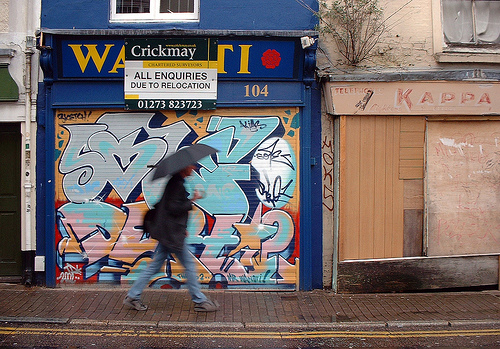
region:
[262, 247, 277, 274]
part of a graphic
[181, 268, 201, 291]
part of a jeans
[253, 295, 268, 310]
part of a floor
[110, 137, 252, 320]
A person in the foreground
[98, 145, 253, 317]
Person is walking on the sidewalk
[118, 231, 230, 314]
Person is wearing jeans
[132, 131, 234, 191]
Person is holding an umbrella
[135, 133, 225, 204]
Umbrella is black in color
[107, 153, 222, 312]
A side view of a person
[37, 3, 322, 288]
A blue colored building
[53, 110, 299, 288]
Graffiti is in the front of the building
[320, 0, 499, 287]
A tan colored building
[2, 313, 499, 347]
A long yellow line in the street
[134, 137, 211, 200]
person is holding black umbrella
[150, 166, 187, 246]
person is wearing black jacket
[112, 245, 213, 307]
person is wearing blue jeans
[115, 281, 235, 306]
person is wearing dark brown shoes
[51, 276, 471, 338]
person is walking on dark red sidewalk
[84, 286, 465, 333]
sidewalk is made of dark brown brick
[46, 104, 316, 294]
multicolor graffiti mural is behind man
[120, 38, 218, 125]
yellow and black real estate sign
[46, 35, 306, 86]
blue and yellow sign over graffiti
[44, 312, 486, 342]
double yellow line on brick sidewalk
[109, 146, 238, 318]
Woman walking down the sidewalk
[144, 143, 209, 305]
they are holding an umbrella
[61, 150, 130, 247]
graffiti on the wall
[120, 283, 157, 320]
person is wearing tennis shoes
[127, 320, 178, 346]
yellow paint on the road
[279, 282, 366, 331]
The sidewalk is uneven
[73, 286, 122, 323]
Sidewalk is made up of brick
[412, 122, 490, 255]
The door is boarded up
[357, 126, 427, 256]
Panels on the wall of building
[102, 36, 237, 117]
Realty sign on building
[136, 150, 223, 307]
this is a man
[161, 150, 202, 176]
this is a umbrella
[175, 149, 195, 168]
the umbrella is black in color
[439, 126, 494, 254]
this is a wall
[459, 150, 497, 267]
the wall is brown in color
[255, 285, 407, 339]
this is the footpath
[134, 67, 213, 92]
this is a writing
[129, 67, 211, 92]
the writing is in black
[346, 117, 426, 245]
this is the door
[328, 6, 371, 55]
this is a tree